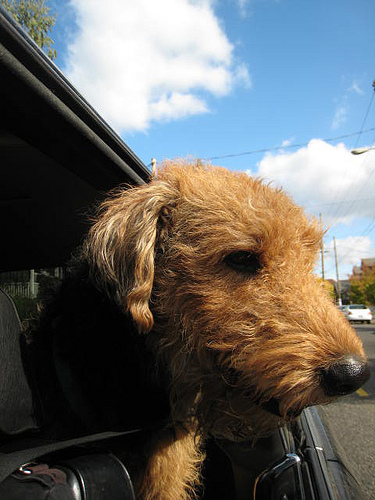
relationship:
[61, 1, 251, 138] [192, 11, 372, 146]
cloud in sky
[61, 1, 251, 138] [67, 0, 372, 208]
cloud in sky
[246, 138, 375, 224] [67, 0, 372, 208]
cloud in sky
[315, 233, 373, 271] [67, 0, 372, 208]
clouds in sky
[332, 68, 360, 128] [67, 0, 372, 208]
clouds in sky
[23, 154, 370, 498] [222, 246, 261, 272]
dog right eye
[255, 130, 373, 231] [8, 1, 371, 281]
cloud in sky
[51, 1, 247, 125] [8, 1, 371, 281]
cloud in sky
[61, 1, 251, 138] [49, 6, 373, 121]
cloud in sky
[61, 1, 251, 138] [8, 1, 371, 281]
cloud in sky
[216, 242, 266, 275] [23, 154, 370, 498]
eye of dog